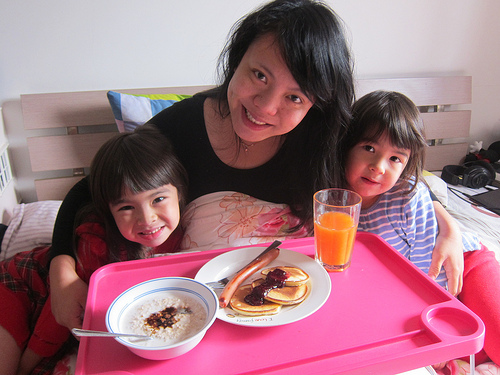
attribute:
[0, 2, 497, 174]
wall — white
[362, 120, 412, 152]
forehead — girl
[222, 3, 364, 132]
hair — black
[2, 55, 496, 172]
bench — wooden 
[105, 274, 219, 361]
bowl — white , round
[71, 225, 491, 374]
pink tray — large 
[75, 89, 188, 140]
pillow — part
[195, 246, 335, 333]
plate — white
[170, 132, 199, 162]
shirt — black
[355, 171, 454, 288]
shirt — plaid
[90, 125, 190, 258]
girl — black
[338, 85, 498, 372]
girl — little